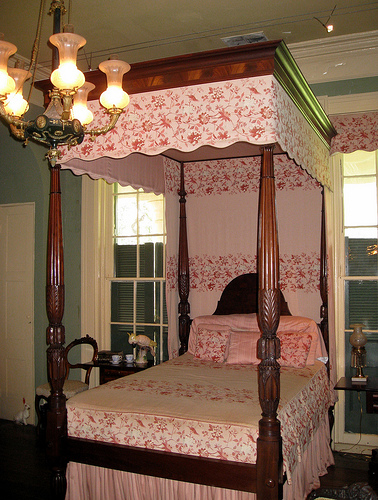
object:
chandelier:
[0, 0, 131, 171]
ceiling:
[1, 1, 377, 119]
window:
[109, 182, 170, 358]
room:
[1, 1, 377, 500]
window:
[340, 147, 378, 439]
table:
[334, 369, 377, 415]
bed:
[31, 40, 335, 495]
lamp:
[349, 323, 367, 381]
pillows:
[194, 322, 313, 369]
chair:
[34, 332, 99, 439]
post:
[254, 143, 282, 500]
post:
[44, 149, 71, 500]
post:
[177, 161, 193, 357]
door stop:
[14, 396, 30, 426]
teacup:
[112, 355, 123, 363]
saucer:
[110, 360, 122, 364]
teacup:
[126, 354, 134, 361]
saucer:
[124, 359, 135, 363]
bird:
[127, 332, 158, 365]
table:
[85, 358, 156, 384]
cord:
[336, 392, 363, 459]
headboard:
[211, 273, 292, 317]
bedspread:
[67, 351, 340, 486]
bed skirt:
[65, 414, 336, 500]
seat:
[34, 379, 82, 421]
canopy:
[35, 40, 335, 198]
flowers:
[91, 377, 253, 414]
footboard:
[67, 435, 261, 499]